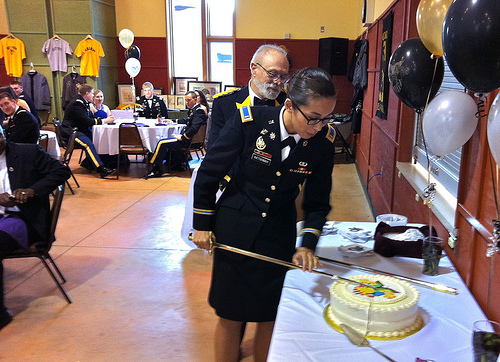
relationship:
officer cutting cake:
[190, 65, 341, 360] [314, 258, 433, 341]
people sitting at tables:
[53, 62, 195, 132] [8, 102, 196, 274]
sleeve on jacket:
[193, 100, 243, 242] [186, 104, 347, 269]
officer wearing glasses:
[190, 65, 341, 360] [288, 96, 336, 136]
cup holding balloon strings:
[418, 236, 447, 275] [420, 154, 436, 240]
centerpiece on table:
[395, 10, 498, 285] [262, 217, 499, 359]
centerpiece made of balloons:
[395, 10, 498, 285] [385, 9, 498, 227]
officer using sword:
[190, 65, 341, 360] [184, 228, 399, 293]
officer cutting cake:
[190, 65, 341, 360] [321, 268, 430, 341]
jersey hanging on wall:
[0, 33, 26, 79] [3, 1, 90, 34]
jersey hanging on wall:
[37, 32, 72, 73] [3, 1, 90, 34]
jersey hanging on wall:
[74, 33, 105, 78] [3, 1, 90, 34]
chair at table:
[117, 123, 150, 175] [87, 113, 187, 167]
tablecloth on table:
[93, 122, 182, 153] [87, 113, 187, 167]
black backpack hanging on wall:
[352, 40, 367, 90] [350, 0, 499, 330]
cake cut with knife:
[338, 250, 465, 329] [186, 229, 386, 294]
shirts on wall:
[8, 34, 108, 82] [5, 0, 165, 138]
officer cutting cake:
[190, 65, 341, 360] [302, 234, 437, 352]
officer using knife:
[190, 65, 341, 360] [285, 251, 394, 322]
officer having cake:
[190, 65, 341, 360] [323, 270, 424, 337]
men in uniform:
[146, 100, 211, 170] [191, 95, 339, 324]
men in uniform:
[146, 100, 211, 170] [55, 92, 105, 174]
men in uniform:
[146, 100, 211, 170] [13, 92, 45, 133]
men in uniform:
[146, 100, 211, 170] [0, 102, 43, 146]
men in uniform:
[146, 100, 211, 170] [0, 139, 72, 311]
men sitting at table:
[146, 100, 211, 170] [89, 114, 189, 182]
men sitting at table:
[146, 100, 211, 170] [262, 217, 499, 359]